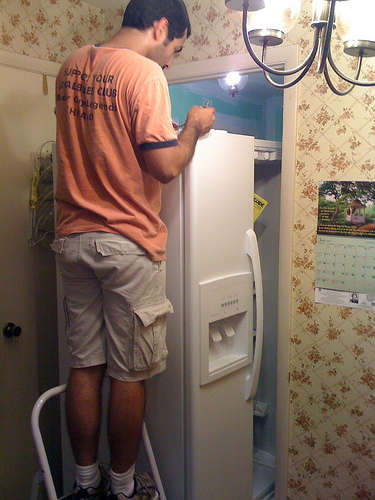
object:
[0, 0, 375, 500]
wallpaper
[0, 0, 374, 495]
wall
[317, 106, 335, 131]
bad sentance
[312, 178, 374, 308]
calendar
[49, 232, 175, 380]
cargo shorts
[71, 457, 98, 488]
socks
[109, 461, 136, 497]
sneaker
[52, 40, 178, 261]
shirt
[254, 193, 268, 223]
paper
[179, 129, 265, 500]
refrigerator door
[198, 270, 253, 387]
dispenser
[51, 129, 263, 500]
freezer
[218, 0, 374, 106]
chandelier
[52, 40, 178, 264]
tee shirt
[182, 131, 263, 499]
door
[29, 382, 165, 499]
step stool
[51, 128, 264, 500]
refrigerator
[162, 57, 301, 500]
doorway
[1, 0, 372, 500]
kitchen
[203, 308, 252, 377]
ice maker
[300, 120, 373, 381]
wall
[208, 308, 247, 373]
dispenser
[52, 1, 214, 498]
man